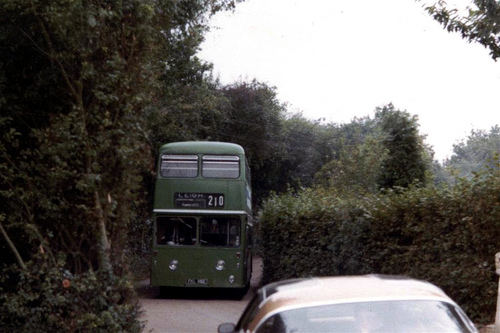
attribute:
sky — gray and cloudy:
[191, 3, 498, 164]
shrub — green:
[5, 216, 154, 331]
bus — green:
[145, 119, 270, 309]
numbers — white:
[201, 188, 231, 211]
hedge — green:
[256, 165, 496, 330]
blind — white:
[163, 152, 198, 174]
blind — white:
[199, 153, 241, 178]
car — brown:
[217, 273, 480, 331]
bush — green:
[272, 203, 437, 331]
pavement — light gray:
[154, 302, 197, 331]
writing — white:
[206, 192, 226, 209]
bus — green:
[143, 129, 259, 297]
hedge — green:
[262, 186, 477, 302]